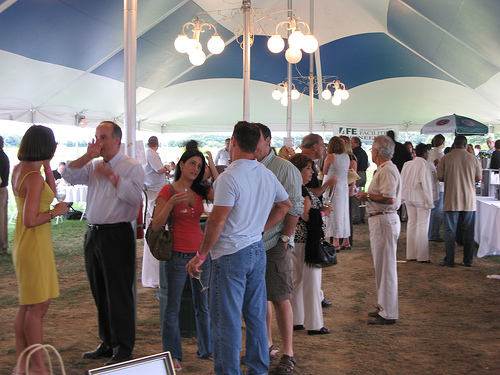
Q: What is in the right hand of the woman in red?
A: A wine glass.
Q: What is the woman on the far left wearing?
A: A yellow dress.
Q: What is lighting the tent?
A: Overhead chandeliers.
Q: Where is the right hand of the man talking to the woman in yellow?
A: In front of his face.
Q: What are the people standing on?
A: Dirt.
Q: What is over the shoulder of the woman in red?
A: A brown purse.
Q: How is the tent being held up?
A: Four tall poles.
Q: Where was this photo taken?
A: In a party tent.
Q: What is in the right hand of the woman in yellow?
A: A wine glass.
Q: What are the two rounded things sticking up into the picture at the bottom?
A: Handles of a bag.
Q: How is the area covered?
A: Tent.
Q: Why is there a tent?
A: Block sun or rain.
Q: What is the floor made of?
A: Dirt.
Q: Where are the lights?
A: Hanging from above.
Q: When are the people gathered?
A: During the the light of day.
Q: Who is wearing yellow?
A: Woman on left.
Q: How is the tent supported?
A: Poles.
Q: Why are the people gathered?
A: For an event.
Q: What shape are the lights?
A: Round.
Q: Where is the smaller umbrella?
A: Right rear.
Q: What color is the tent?
A: Blue and white.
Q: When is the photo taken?
A: Daytime.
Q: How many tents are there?
A: One.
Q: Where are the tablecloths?
A: On the table.